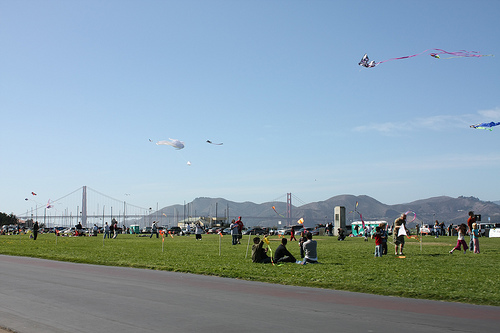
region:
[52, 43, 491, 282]
people in a park flying kites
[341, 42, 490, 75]
kite with long pink tails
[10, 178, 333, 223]
bridge in the distance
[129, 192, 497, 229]
small mountains in the landscape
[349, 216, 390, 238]
row of outhouses at park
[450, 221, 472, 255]
girl with white top and burgandy capris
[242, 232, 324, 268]
people sitting on grass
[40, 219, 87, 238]
vehicles parked on the grass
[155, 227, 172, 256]
orange marker flag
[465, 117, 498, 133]
blue and green kite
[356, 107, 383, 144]
part of a cloud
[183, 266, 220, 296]
part of a road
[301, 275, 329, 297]
edge of a road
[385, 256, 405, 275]
part of a field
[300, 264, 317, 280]
part of a field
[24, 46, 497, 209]
kites flying in the air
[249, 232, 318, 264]
people sitting on the grass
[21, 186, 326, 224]
large bridge structure in the distance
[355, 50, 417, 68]
kite in the air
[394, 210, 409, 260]
man holding a white kite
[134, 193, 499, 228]
gray mountains in the distance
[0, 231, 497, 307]
green grass on the ground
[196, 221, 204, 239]
person flying a kite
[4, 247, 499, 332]
street next to the field of grass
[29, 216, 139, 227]
body of water under the bridge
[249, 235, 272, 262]
a person sitting in grass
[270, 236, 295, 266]
a person sitting in grass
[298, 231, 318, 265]
a person sitting in grass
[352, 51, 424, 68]
a kite flying in air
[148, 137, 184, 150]
a kite flying in air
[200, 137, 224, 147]
a kite flying in air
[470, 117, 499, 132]
a kite flying in air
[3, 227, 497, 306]
a green grassy field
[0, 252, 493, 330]
a paved road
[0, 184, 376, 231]
a long suspension bridge in distance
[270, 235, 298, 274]
This is a person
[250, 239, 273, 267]
This is a person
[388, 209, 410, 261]
This is a person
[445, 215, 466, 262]
This is a person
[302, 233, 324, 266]
This is a person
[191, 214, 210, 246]
This is a person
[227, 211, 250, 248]
This is a person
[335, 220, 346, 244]
This is a person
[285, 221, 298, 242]
This is a person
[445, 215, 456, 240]
This is a person